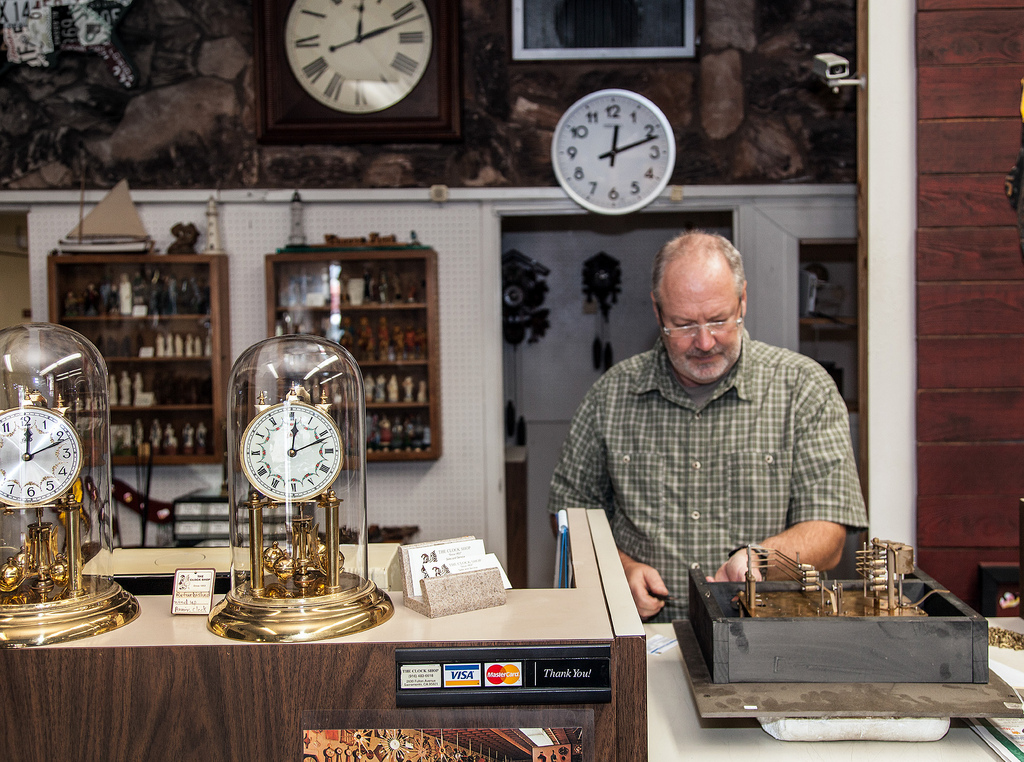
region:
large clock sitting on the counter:
[202, 304, 398, 659]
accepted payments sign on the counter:
[385, 648, 611, 712]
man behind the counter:
[548, 244, 893, 638]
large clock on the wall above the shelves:
[245, 16, 471, 152]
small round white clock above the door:
[539, 60, 685, 234]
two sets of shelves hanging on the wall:
[36, 236, 449, 458]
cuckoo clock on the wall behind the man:
[567, 236, 626, 391]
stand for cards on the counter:
[387, 533, 495, 616]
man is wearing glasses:
[662, 265, 799, 415]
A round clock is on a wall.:
[549, 83, 683, 214]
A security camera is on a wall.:
[808, 50, 859, 92]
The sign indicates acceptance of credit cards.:
[397, 644, 612, 703]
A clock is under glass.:
[210, 333, 389, 638]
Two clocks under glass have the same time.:
[0, 323, 386, 640]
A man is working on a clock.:
[547, 222, 1006, 728]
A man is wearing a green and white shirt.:
[549, 328, 869, 622]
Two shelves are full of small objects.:
[55, 242, 448, 461]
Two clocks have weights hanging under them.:
[500, 245, 621, 435]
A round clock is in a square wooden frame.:
[258, 0, 473, 150]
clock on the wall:
[545, 82, 681, 228]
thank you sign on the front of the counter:
[532, 653, 609, 695]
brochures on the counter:
[390, 525, 512, 614]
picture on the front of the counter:
[289, 711, 618, 756]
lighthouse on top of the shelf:
[279, 186, 306, 250]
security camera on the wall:
[801, 29, 872, 97]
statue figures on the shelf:
[73, 265, 206, 316]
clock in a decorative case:
[228, 337, 371, 620]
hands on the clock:
[605, 121, 650, 163]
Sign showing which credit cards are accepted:
[397, 654, 528, 693]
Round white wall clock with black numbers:
[549, 81, 682, 221]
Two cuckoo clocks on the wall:
[503, 246, 625, 371]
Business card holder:
[394, 527, 515, 616]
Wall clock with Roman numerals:
[249, 0, 464, 146]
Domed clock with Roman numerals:
[202, 334, 396, 642]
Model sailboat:
[53, 179, 161, 256]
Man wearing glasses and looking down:
[647, 225, 756, 384]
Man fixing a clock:
[544, 227, 1022, 743]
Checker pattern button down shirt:
[550, 331, 870, 613]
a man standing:
[588, 216, 839, 581]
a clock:
[549, 88, 679, 215]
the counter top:
[531, 594, 604, 640]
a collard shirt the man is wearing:
[718, 377, 754, 396]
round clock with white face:
[552, 84, 679, 220]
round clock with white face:
[244, 394, 346, 493]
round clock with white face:
[4, 409, 80, 512]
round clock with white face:
[278, 3, 435, 120]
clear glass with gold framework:
[208, 333, 395, 641]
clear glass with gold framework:
[3, 312, 141, 646]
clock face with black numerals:
[239, 394, 348, 502]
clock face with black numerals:
[3, 407, 79, 509]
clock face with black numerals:
[554, 84, 678, 215]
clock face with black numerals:
[282, 8, 438, 120]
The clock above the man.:
[540, 89, 695, 236]